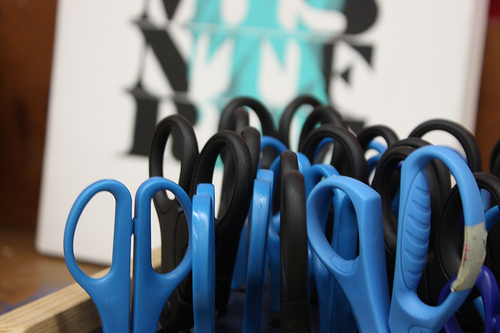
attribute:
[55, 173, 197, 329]
scissors — blue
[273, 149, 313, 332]
scissors — black, black.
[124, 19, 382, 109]
word — written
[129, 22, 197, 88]
n — black, board, written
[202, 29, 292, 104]
t — blue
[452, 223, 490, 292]
handle — gray, blue, black \, big, left\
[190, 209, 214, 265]
part — shiny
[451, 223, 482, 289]
scissors — white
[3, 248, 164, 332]
container — wooden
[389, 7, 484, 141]
canas — white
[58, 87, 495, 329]
scissors. — black.\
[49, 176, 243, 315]
scissors — blue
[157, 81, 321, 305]
scissors... — blue..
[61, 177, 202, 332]
scissors — blue